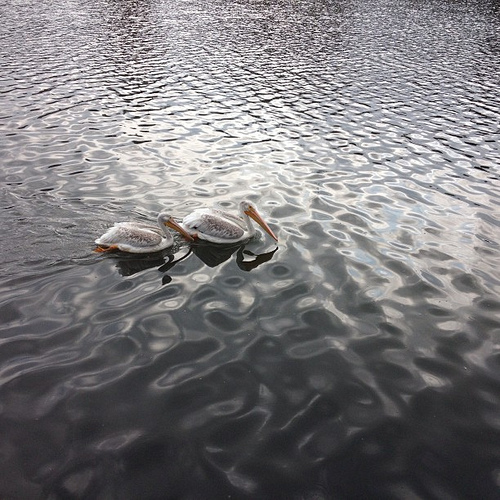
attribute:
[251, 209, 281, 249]
beak — orange